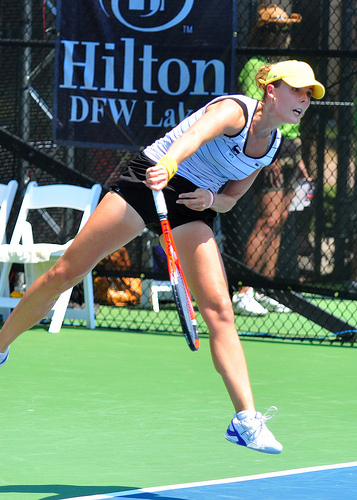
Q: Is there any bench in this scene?
A: No, there are no benches.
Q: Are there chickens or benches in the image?
A: No, there are no benches or chickens.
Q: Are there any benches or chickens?
A: No, there are no benches or chickens.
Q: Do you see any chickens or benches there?
A: No, there are no benches or chickens.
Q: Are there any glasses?
A: No, there are no glasses.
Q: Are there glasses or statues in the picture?
A: No, there are no glasses or statues.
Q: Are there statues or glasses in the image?
A: No, there are no glasses or statues.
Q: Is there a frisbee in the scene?
A: No, there are no frisbees.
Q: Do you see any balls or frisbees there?
A: No, there are no frisbees or balls.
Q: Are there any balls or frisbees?
A: No, there are no frisbees or balls.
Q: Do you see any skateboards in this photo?
A: No, there are no skateboards.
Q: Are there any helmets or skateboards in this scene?
A: No, there are no skateboards or helmets.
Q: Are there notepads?
A: No, there are no notepads.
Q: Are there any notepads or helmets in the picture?
A: No, there are no notepads or helmets.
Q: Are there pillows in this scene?
A: No, there are no pillows.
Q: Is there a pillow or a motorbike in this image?
A: No, there are no pillows or motorcycles.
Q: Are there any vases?
A: No, there are no vases.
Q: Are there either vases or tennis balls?
A: No, there are no vases or tennis balls.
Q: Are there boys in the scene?
A: No, there are no boys.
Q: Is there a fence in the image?
A: Yes, there is a fence.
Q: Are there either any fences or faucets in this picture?
A: Yes, there is a fence.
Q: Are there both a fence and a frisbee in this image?
A: No, there is a fence but no frisbees.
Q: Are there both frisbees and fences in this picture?
A: No, there is a fence but no frisbees.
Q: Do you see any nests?
A: No, there are no nests.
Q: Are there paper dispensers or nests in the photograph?
A: No, there are no nests or paper dispensers.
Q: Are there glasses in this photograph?
A: No, there are no glasses.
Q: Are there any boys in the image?
A: No, there are no boys.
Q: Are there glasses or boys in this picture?
A: No, there are no boys or glasses.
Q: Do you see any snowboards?
A: No, there are no snowboards.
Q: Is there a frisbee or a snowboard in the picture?
A: No, there are no snowboards or frisbees.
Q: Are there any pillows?
A: No, there are no pillows.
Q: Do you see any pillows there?
A: No, there are no pillows.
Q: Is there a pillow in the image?
A: No, there are no pillows.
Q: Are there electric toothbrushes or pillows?
A: No, there are no pillows or electric toothbrushes.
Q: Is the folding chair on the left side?
A: Yes, the folding chair is on the left of the image.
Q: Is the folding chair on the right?
A: No, the folding chair is on the left of the image.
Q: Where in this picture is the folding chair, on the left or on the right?
A: The folding chair is on the left of the image.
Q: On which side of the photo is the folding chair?
A: The folding chair is on the left of the image.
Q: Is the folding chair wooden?
A: Yes, the folding chair is wooden.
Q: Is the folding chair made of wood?
A: Yes, the folding chair is made of wood.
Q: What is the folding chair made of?
A: The folding chair is made of wood.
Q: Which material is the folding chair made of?
A: The folding chair is made of wood.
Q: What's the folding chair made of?
A: The folding chair is made of wood.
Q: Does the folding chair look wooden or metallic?
A: The folding chair is wooden.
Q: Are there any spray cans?
A: No, there are no spray cans.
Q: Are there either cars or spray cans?
A: No, there are no spray cans or cars.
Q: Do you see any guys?
A: No, there are no guys.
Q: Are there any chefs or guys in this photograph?
A: No, there are no guys or chefs.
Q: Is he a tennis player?
A: Yes, this is a tennis player.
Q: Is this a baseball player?
A: No, this is a tennis player.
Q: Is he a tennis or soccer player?
A: This is a tennis player.